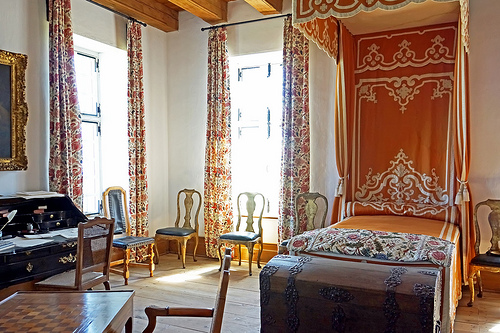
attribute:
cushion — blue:
[216, 225, 264, 242]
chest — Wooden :
[249, 250, 438, 330]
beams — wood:
[98, 2, 268, 32]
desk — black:
[1, 186, 100, 291]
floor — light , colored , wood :
[92, 237, 499, 331]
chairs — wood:
[87, 171, 287, 273]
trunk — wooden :
[255, 247, 442, 332]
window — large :
[201, 20, 345, 237]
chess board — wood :
[18, 259, 173, 331]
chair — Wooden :
[102, 188, 152, 283]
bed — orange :
[287, 196, 465, 317]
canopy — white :
[290, 0, 479, 269]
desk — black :
[6, 193, 106, 289]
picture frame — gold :
[2, 58, 27, 168]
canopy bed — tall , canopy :
[290, 0, 473, 329]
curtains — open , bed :
[336, 28, 464, 222]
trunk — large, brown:
[247, 249, 453, 331]